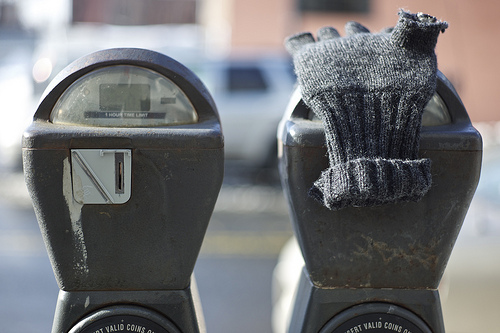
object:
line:
[198, 231, 293, 255]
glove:
[282, 8, 447, 212]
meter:
[269, 70, 483, 332]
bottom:
[306, 154, 433, 211]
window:
[224, 64, 272, 94]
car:
[174, 49, 300, 184]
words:
[134, 112, 149, 120]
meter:
[22, 46, 225, 332]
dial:
[319, 300, 434, 333]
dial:
[47, 64, 198, 129]